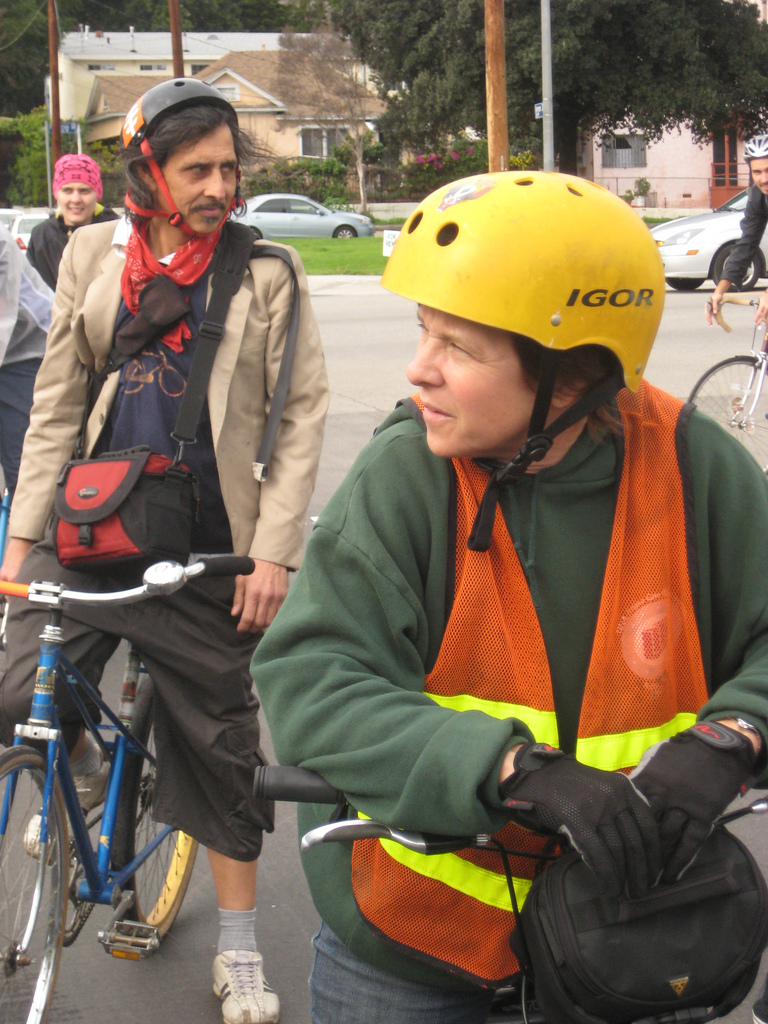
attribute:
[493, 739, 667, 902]
glove — black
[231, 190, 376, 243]
car — side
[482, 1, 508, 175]
pole — tall, brown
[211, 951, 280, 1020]
sneaker — white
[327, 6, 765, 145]
leaves — green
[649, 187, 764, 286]
car — silver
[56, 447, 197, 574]
bag — red, black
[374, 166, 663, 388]
helmet — yellow, person's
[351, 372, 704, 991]
vest — orange, reflective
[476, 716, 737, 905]
gloves — black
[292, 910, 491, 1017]
jeans — blue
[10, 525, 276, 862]
shorts — grey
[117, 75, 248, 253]
helmet — black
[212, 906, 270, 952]
sock — grey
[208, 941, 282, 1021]
shoe — white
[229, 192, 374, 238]
vehicle — grey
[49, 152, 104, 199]
hat — pink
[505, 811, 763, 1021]
bag — black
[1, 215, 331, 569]
suit jacket — tan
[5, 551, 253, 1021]
bike — blue, silver, black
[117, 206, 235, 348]
scarf — red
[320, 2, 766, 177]
tree — large, huge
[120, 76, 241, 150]
helmet — black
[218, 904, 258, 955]
sock — grey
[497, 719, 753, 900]
gloves — black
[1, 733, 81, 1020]
tire — view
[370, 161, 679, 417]
helmet — view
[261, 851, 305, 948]
road — view